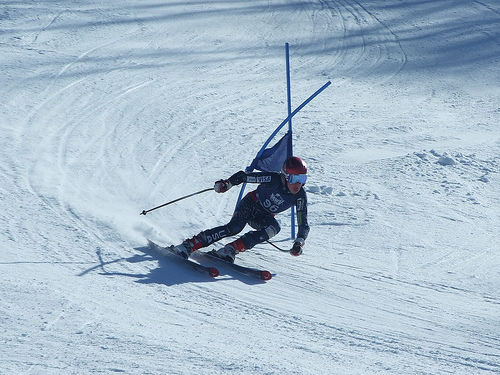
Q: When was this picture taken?
A: During the day.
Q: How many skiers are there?
A: One.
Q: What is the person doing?
A: Skiing.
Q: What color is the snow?
A: White.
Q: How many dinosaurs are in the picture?
A: Zero.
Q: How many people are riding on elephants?
A: Zero.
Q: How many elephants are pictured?
A: Zero.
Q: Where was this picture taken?
A: On a ski slope.